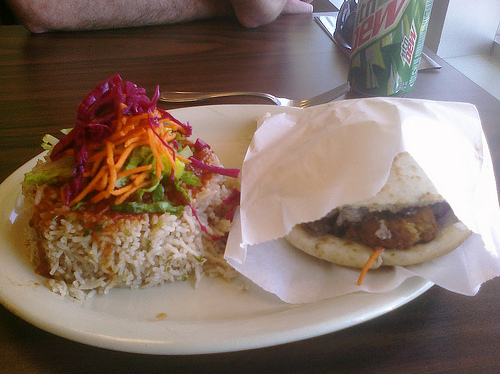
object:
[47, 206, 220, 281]
meal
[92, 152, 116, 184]
carrots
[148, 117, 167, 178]
carrots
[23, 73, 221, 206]
meal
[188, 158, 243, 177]
cabbage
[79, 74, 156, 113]
cabbage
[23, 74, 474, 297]
meal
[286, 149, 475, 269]
meal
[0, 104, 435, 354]
plate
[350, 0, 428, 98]
can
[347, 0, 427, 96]
soda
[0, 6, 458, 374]
table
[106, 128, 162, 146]
carrots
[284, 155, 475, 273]
hamburger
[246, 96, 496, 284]
paper work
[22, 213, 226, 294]
rice patty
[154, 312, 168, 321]
crumbs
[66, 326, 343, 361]
edge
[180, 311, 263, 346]
portion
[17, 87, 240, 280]
food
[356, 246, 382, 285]
carrot piece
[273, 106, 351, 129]
crinkle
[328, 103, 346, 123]
crinkle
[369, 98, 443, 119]
crinkle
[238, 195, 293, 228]
crinkle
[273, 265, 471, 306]
edge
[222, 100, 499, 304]
bag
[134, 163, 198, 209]
lettuce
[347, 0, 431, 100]
soda can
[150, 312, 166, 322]
crumb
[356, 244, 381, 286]
carrot slice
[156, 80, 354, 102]
fork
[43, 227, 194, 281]
rice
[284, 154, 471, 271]
bun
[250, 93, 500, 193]
paper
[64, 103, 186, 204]
vegetable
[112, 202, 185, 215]
lettuce sliver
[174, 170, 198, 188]
lettuce sliver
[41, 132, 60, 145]
lettuce sliver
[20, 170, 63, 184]
lettuce sliver